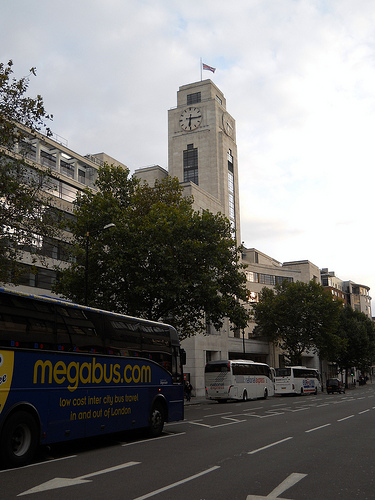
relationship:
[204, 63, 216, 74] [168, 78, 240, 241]
flag on a tower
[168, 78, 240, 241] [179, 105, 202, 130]
tower has a clock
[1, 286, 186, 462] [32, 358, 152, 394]
bus has a ad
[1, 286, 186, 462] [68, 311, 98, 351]
bus has a window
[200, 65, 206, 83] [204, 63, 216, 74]
pole has a flag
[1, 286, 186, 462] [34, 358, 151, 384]
bus has an ad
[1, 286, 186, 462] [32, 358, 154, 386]
bus says megabus.com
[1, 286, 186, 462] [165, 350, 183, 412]
bus has a door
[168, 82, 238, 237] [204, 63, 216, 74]
building has a flag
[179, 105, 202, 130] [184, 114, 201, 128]
clock has a face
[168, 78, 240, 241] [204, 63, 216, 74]
tower has a flag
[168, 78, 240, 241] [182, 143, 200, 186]
tower has a window